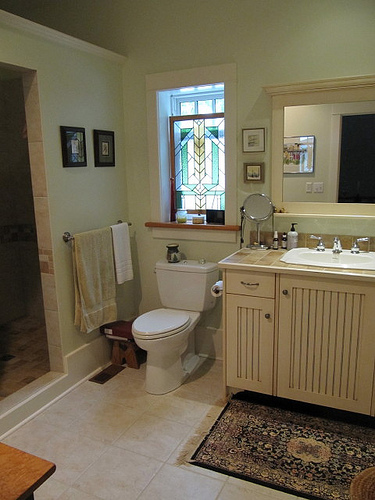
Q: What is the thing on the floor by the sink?
A: Rug.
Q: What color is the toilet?
A: White.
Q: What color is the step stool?
A: Brown.